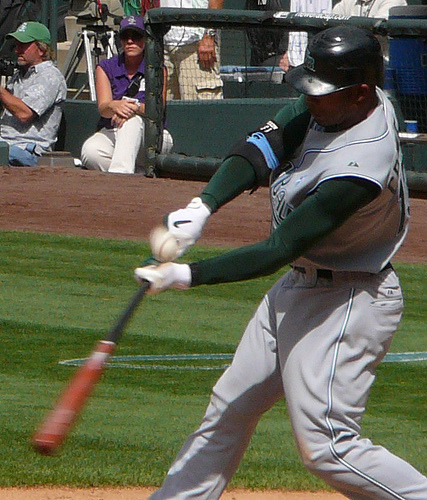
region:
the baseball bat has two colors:
[32, 253, 178, 465]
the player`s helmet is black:
[274, 1, 387, 103]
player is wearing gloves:
[131, 187, 231, 301]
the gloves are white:
[132, 192, 202, 296]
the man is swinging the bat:
[23, 12, 422, 474]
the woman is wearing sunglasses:
[107, 1, 147, 58]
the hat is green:
[3, 19, 54, 54]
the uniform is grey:
[193, 18, 424, 498]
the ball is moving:
[112, 217, 195, 295]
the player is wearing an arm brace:
[201, 107, 318, 189]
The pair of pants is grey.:
[256, 283, 402, 476]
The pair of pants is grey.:
[288, 236, 384, 450]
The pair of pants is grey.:
[267, 279, 355, 441]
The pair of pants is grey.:
[229, 293, 349, 494]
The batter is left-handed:
[95, 15, 425, 496]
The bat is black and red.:
[27, 237, 197, 459]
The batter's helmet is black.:
[276, 24, 393, 105]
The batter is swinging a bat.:
[2, 3, 422, 495]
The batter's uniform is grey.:
[148, 88, 401, 497]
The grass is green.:
[1, 229, 423, 490]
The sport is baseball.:
[4, 0, 421, 495]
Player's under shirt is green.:
[168, 86, 397, 311]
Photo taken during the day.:
[8, 16, 422, 496]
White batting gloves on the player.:
[119, 180, 231, 309]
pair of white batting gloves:
[131, 195, 212, 295]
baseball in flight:
[143, 225, 182, 260]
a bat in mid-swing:
[31, 209, 188, 464]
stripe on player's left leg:
[325, 288, 406, 497]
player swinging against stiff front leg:
[148, 292, 274, 495]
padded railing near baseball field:
[139, 6, 425, 196]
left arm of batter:
[186, 168, 376, 282]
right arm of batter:
[198, 93, 301, 213]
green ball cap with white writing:
[6, 18, 54, 50]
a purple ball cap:
[115, 7, 151, 35]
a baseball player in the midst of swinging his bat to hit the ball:
[35, 15, 410, 498]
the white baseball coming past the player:
[145, 224, 178, 266]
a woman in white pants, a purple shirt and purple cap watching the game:
[83, 18, 159, 174]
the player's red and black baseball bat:
[16, 244, 180, 462]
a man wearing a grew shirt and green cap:
[6, 16, 67, 179]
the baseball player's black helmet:
[274, 19, 388, 96]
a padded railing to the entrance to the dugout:
[139, 5, 176, 181]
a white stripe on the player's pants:
[327, 298, 348, 471]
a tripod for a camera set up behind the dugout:
[52, 5, 122, 109]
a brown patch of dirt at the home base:
[6, 484, 141, 498]